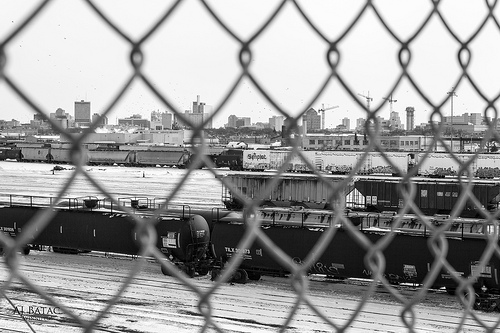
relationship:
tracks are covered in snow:
[15, 231, 486, 333] [84, 286, 115, 315]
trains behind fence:
[206, 142, 496, 302] [6, 5, 496, 331]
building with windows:
[21, 106, 496, 179] [301, 127, 376, 153]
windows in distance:
[301, 127, 376, 153] [3, 7, 498, 330]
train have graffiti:
[239, 146, 497, 177] [254, 166, 495, 178]